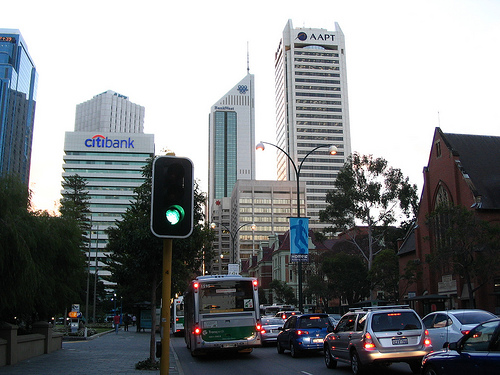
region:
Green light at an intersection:
[150, 154, 194, 239]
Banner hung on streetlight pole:
[287, 215, 309, 258]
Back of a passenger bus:
[182, 274, 262, 357]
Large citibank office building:
[59, 90, 154, 325]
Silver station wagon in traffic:
[322, 304, 433, 373]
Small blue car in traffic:
[276, 313, 336, 354]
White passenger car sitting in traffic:
[418, 308, 498, 350]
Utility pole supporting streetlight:
[159, 238, 173, 373]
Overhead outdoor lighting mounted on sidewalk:
[252, 139, 340, 311]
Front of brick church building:
[393, 125, 498, 311]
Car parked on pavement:
[325, 264, 412, 374]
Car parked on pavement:
[425, 308, 483, 373]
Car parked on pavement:
[275, 292, 341, 365]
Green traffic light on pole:
[145, 144, 198, 245]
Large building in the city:
[64, 67, 156, 374]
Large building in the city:
[220, 163, 315, 287]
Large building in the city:
[192, 66, 270, 289]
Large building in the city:
[260, 5, 364, 285]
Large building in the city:
[1, 22, 58, 235]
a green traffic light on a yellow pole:
[147, 150, 192, 371]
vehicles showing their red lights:
[170, 271, 495, 371]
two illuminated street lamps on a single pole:
[252, 140, 337, 312]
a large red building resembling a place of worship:
[395, 125, 495, 307]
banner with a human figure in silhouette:
[287, 217, 308, 259]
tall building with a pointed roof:
[211, 76, 255, 196]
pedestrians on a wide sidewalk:
[18, 311, 175, 374]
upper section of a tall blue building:
[0, 28, 37, 182]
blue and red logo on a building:
[65, 89, 152, 293]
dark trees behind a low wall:
[0, 178, 62, 365]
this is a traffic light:
[140, 153, 217, 235]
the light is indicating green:
[161, 206, 196, 220]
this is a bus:
[184, 274, 269, 346]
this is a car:
[343, 298, 401, 357]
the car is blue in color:
[301, 334, 326, 345]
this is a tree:
[308, 159, 393, 275]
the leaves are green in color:
[338, 187, 372, 210]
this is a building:
[282, 17, 362, 137]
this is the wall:
[233, 113, 251, 166]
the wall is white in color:
[237, 111, 255, 163]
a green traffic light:
[135, 137, 215, 257]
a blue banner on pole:
[276, 209, 319, 271]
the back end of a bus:
[182, 267, 286, 367]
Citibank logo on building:
[80, 127, 155, 156]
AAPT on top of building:
[293, 27, 343, 51]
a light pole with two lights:
[235, 123, 360, 314]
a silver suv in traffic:
[308, 300, 433, 373]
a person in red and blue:
[105, 308, 125, 335]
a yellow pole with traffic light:
[155, 237, 178, 374]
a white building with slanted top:
[196, 47, 275, 262]